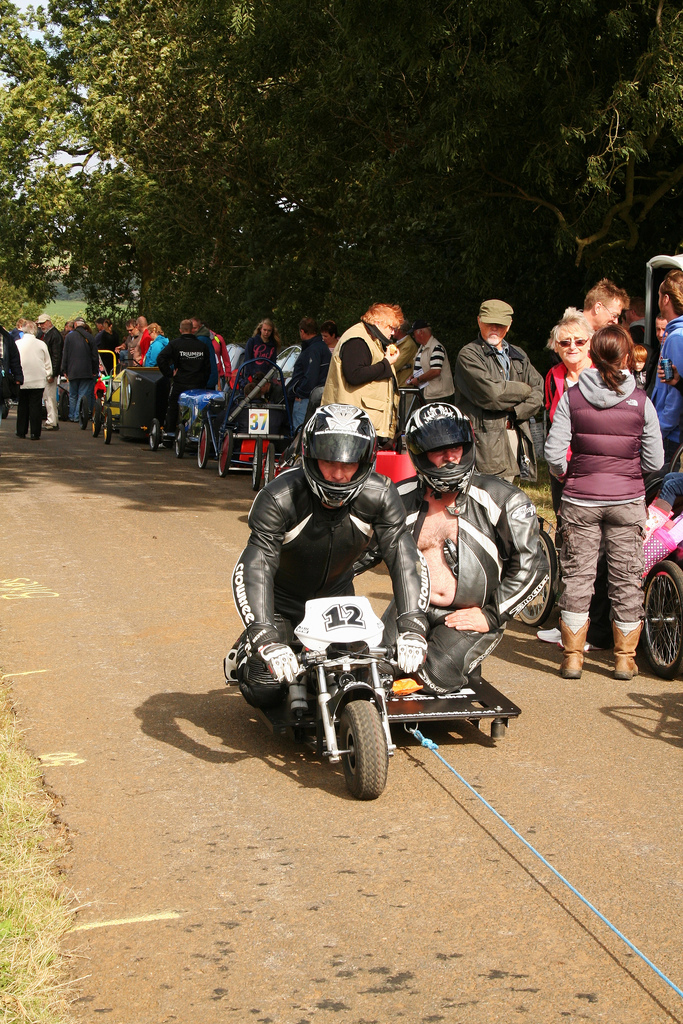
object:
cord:
[417, 731, 678, 1000]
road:
[0, 437, 683, 1024]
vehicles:
[93, 347, 169, 450]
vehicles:
[217, 359, 292, 476]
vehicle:
[511, 512, 682, 673]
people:
[449, 279, 651, 544]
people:
[282, 309, 352, 434]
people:
[102, 314, 223, 446]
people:
[1, 306, 100, 434]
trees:
[3, 6, 93, 289]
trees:
[165, 6, 309, 334]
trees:
[611, 6, 673, 288]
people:
[331, 276, 683, 682]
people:
[164, 302, 445, 433]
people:
[57, 310, 126, 429]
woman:
[542, 327, 667, 680]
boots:
[608, 614, 644, 680]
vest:
[564, 381, 648, 506]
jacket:
[235, 469, 425, 626]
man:
[231, 407, 434, 683]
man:
[379, 403, 537, 695]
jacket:
[387, 469, 543, 630]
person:
[321, 303, 403, 444]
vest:
[320, 322, 395, 434]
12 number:
[323, 602, 365, 632]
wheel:
[336, 699, 386, 800]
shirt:
[413, 339, 444, 382]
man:
[407, 318, 456, 402]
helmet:
[301, 403, 378, 511]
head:
[300, 403, 376, 511]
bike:
[222, 595, 517, 796]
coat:
[545, 368, 665, 506]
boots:
[556, 610, 591, 681]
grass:
[39, 292, 91, 319]